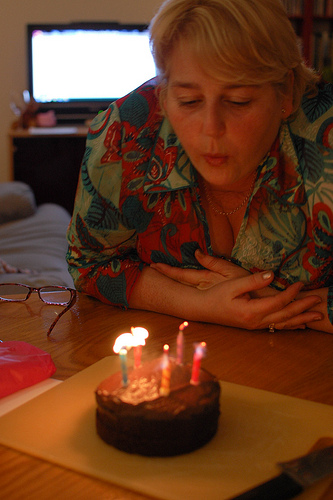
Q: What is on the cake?
A: Candles.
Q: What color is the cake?
A: Brown.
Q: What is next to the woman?
A: Glasses.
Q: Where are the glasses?
A: On the table.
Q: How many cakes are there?
A: One.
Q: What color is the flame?
A: Orange.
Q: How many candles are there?
A: Five.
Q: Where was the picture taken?
A: In a living room.